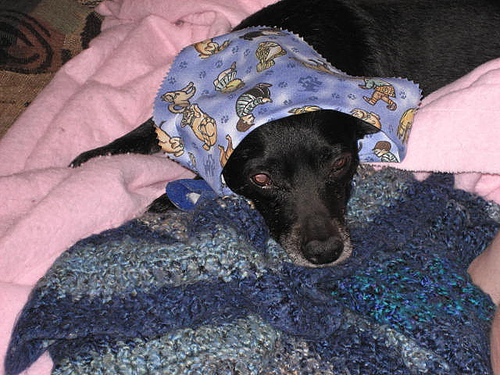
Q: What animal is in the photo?
A: Dog.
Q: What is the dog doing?
A: Laying down.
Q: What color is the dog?
A: Black.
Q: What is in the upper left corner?
A: Carpet.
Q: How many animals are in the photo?
A: One.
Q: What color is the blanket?
A: Pink.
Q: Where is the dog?
A: On a blanket.